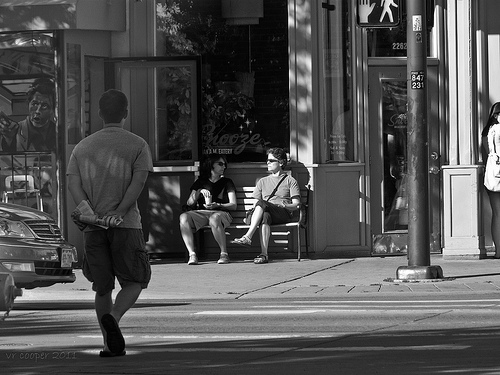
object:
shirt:
[67, 127, 153, 229]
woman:
[176, 150, 241, 267]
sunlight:
[289, 24, 318, 163]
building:
[4, 2, 496, 269]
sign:
[353, 0, 402, 30]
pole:
[404, 0, 430, 266]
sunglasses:
[266, 158, 280, 163]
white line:
[193, 306, 330, 318]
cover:
[2, 269, 25, 315]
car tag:
[60, 251, 72, 268]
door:
[363, 31, 438, 251]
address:
[392, 42, 407, 49]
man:
[64, 90, 155, 358]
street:
[9, 299, 498, 371]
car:
[0, 201, 76, 311]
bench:
[181, 185, 308, 260]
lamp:
[0, 216, 36, 243]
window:
[152, 62, 197, 168]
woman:
[169, 149, 270, 271]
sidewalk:
[0, 252, 500, 309]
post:
[394, 266, 444, 281]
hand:
[104, 210, 124, 229]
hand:
[83, 216, 102, 228]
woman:
[231, 148, 302, 264]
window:
[193, 60, 296, 151]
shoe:
[100, 313, 125, 355]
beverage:
[204, 196, 213, 204]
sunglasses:
[218, 162, 228, 167]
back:
[65, 127, 153, 231]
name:
[196, 122, 267, 156]